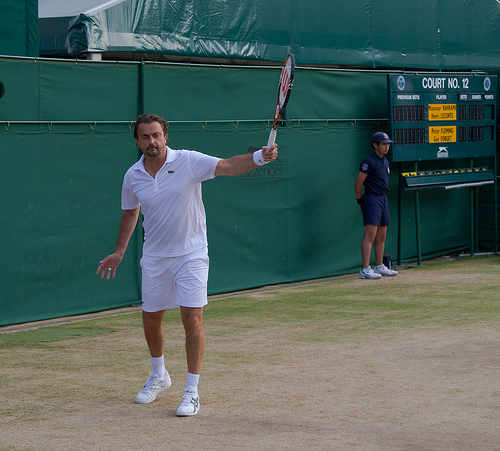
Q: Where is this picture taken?
A: Tennis court.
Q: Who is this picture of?
A: A tennis player.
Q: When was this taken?
A: Daytime.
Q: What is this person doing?
A: Playing tennis.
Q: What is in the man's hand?
A: A tennis racket.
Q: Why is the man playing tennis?
A: Competing in competition.